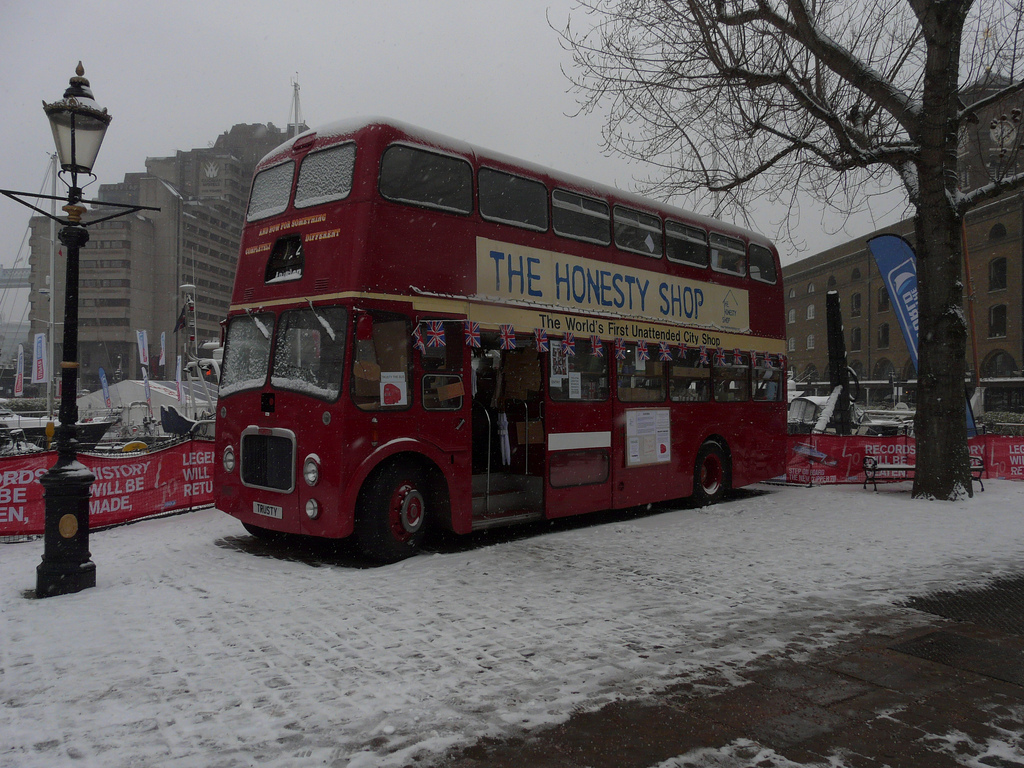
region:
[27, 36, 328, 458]
There is a tall building in the background.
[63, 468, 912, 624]
snow covering the ground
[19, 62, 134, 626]
Tall metal street lamp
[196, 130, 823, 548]
Big red and white bus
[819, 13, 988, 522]
Large tree in front of bench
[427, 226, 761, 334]
Sign with blue letters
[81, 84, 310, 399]
Building in the distance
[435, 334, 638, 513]
Open door on bus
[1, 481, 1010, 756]
Snow covering on the ground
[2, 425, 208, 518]
Red and white banner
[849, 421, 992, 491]
A bench behind tree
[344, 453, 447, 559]
Big red and silver tire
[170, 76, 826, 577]
Double-decker, decorated British bus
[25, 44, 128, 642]
Vintage street lamp and snow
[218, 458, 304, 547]
License plate on front of bus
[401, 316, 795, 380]
British flag decorating bus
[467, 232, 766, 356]
Writing on the side of bus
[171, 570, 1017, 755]
Layer of snow on cobblestone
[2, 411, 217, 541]
Ad slogans on red banners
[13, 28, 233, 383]
Urban structure behind street lamp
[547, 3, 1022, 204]
Leafless tree in winter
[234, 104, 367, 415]
Snow on bus windshields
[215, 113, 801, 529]
bus parked on snowy street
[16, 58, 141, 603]
black iron street lamp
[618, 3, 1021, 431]
tall tree nearbus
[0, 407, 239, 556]
construction fencing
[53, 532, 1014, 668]
snow atop the road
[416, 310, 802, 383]
England flags along the side of the bus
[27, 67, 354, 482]
concrete building in the background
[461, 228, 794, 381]
advertisement along the side of the bus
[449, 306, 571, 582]
doorway leading into the bus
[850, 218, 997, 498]
advertising sign behind the tree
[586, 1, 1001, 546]
Tree with no leaves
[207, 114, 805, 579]
Double decker red bus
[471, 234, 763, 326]
Advertisement sign on side of bus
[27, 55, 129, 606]
Street lamp post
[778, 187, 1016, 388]
Brick building behind bus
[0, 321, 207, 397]
Red, white and blue banners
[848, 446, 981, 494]
Black metal park bench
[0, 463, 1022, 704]
Light snow covering the ground.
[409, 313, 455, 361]
Small flag hanging from side of bus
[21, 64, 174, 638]
An old-fashioned lamppost, close to bus.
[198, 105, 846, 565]
Double-Decker, red bus with doors open.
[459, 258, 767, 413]
Sign on bus reads, "Honesty Shop."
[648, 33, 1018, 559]
Tall tree with bare branches.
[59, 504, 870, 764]
Light layer of snow, covering old, weathered, pavement.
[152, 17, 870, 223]
Dull, grey-tinged, winter sky.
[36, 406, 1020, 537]
Red barrier with lettering on it.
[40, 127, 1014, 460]
Two, tall buildings behind bus, in distance.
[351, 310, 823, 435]
Numerous, small British flags, decorating bus.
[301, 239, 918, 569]
No one clearly, visible on bus.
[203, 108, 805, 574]
large double decker bus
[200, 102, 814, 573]
big red bus parked in the snow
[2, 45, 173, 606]
pretty lamp post covered in snow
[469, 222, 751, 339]
big sign saying The Honesty Shop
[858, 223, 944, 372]
part of a blue banner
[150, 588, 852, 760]
partially snow covered sidewalk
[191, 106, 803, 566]
city shop in a double decker bus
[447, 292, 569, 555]
open doorway to inside of bus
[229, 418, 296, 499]
bus radiator grill